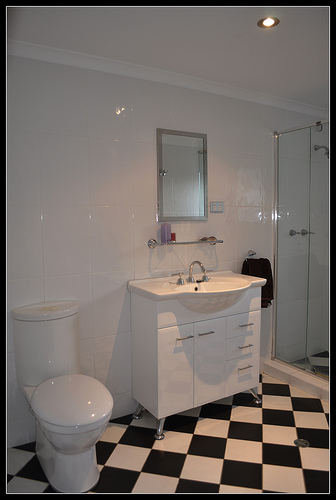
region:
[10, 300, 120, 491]
White toilet in bathroom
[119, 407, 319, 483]
Black and white bathroom tile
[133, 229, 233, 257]
Silver towel rack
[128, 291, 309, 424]
White bathroom vanity with silver hardware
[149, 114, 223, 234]
Over the sink mirror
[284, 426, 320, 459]
Silver floor drain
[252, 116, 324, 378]
Clear shower door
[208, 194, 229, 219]
Wall outlet next to mirror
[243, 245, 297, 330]
Brown towel on towel rack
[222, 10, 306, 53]
recessed light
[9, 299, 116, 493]
a white toilet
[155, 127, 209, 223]
a mirror on bathroom wall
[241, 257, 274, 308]
a towel hanging on a towel rack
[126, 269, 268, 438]
a bathroom sink with cabinet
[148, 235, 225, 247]
a towel rack on the wall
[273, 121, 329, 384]
a bathroom shower stall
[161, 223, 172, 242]
a candle sitting on a towel rack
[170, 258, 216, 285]
a bathroom sink faucet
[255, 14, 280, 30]
a light on a bathroom ceiling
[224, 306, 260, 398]
drawers on a bathroom sink cabinet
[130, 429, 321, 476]
The bathroom floor has black and white tiles.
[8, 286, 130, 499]
The toilet is white in color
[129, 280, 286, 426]
The sink base is white in color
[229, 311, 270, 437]
The sink base has 3 drawers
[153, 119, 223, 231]
The bathroom has a rectangular mirror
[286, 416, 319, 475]
The floor has a water drain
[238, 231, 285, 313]
A black towel is hanging on the wall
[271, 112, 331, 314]
The shower doors are clear glass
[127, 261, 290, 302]
The sink is a light beige color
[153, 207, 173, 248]
A purple candle is placed on a shelf about the sink.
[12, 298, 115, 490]
a sparkling clean toilet.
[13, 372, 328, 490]
black and white checkered floor.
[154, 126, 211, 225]
vanity mirror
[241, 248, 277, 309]
clean towel hanging on towel ring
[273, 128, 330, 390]
see through shower doors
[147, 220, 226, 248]
shelf in bathroom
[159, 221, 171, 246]
light purple candle on shelf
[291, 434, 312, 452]
drain hole in case water is on the floor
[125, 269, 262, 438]
bathroom sink and cabinets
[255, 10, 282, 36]
bright light for the bathroom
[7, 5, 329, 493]
sparkling clean home bathroom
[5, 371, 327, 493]
black and white checkered tile floor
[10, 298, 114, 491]
white toilet and tank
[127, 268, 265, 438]
white cabinet and sink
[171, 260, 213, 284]
silver chrome faucet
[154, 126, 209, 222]
silver framed medicine cabinet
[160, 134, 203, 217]
rectangular bathroom mirror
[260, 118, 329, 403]
glass walled shower enclosure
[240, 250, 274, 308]
brown bath towel on hook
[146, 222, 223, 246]
toiletries on glass shelf